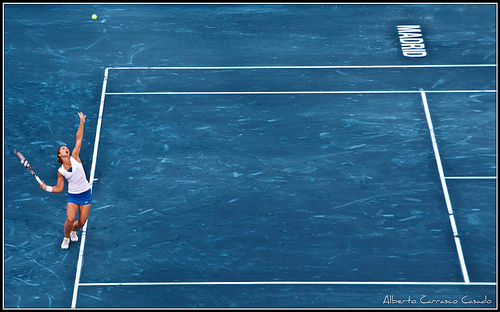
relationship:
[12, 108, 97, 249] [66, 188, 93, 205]
woman has blue shorts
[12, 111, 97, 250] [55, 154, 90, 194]
woman has top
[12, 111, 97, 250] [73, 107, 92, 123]
woman has hand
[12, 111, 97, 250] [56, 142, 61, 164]
woman has hair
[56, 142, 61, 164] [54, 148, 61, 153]
hair has part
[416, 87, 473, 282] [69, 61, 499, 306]
white line on court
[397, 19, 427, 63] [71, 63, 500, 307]
writing on court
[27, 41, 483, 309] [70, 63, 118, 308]
court has white baseline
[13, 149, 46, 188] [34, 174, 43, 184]
racket in hand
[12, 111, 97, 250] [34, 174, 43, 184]
woman has hand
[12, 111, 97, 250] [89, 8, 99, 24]
woman serving tennis ball